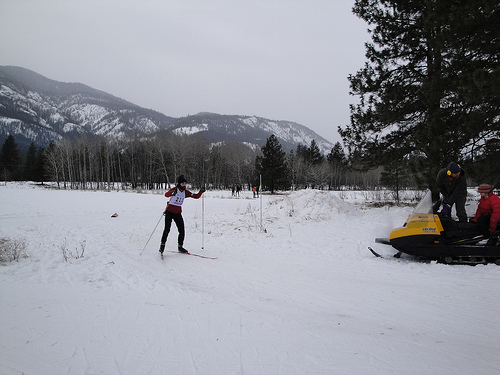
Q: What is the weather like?
A: It is cloudy.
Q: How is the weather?
A: It is cloudy.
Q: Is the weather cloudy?
A: Yes, it is cloudy.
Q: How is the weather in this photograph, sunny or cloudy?
A: It is cloudy.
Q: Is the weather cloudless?
A: No, it is cloudy.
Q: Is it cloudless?
A: No, it is cloudy.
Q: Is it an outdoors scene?
A: Yes, it is outdoors.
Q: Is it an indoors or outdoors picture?
A: It is outdoors.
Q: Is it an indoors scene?
A: No, it is outdoors.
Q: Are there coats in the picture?
A: Yes, there is a coat.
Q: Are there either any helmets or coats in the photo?
A: Yes, there is a coat.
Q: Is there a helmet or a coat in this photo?
A: Yes, there is a coat.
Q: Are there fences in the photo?
A: No, there are no fences.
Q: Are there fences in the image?
A: No, there are no fences.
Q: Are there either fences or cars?
A: No, there are no fences or cars.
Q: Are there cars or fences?
A: No, there are no fences or cars.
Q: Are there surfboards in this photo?
A: No, there are no surfboards.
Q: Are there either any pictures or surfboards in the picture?
A: No, there are no surfboards or pictures.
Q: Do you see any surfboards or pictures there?
A: No, there are no surfboards or pictures.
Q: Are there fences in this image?
A: No, there are no fences.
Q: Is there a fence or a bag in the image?
A: No, there are no fences or bags.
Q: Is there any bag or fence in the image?
A: No, there are no fences or bags.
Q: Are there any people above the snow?
A: Yes, there is a person above the snow.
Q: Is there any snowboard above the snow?
A: No, there is a person above the snow.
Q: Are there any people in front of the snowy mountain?
A: Yes, there is a person in front of the mountain.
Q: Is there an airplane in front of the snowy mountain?
A: No, there is a person in front of the mountain.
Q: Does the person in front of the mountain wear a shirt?
A: Yes, the person wears a shirt.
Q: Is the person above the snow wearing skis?
A: Yes, the person is wearing skis.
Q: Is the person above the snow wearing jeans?
A: No, the person is wearing skis.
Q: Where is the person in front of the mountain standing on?
A: The person is standing on the snow.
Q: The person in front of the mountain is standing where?
A: The person is standing on the snow.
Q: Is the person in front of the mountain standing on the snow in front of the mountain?
A: Yes, the person is standing on the snow.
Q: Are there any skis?
A: Yes, there are skis.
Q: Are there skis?
A: Yes, there are skis.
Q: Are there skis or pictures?
A: Yes, there are skis.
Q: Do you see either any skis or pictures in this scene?
A: Yes, there are skis.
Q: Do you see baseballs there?
A: No, there are no baseballs.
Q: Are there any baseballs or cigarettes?
A: No, there are no baseballs or cigarettes.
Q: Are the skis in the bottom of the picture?
A: Yes, the skis are in the bottom of the image.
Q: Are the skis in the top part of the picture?
A: No, the skis are in the bottom of the image.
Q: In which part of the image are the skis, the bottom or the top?
A: The skis are in the bottom of the image.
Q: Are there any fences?
A: No, there are no fences.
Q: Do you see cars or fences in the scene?
A: No, there are no fences or cars.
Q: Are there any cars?
A: No, there are no cars.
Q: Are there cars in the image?
A: No, there are no cars.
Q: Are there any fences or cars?
A: No, there are no cars or fences.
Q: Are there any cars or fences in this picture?
A: No, there are no cars or fences.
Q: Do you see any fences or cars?
A: No, there are no cars or fences.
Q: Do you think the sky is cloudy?
A: Yes, the sky is cloudy.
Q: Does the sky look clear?
A: No, the sky is cloudy.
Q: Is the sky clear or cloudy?
A: The sky is cloudy.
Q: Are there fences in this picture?
A: No, there are no fences.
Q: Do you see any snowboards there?
A: No, there are no snowboards.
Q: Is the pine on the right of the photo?
A: Yes, the pine is on the right of the image.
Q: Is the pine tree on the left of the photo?
A: No, the pine tree is on the right of the image.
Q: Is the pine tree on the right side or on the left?
A: The pine tree is on the right of the image.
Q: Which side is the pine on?
A: The pine is on the right of the image.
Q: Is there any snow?
A: Yes, there is snow.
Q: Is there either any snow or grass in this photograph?
A: Yes, there is snow.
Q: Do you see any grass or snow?
A: Yes, there is snow.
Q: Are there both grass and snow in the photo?
A: No, there is snow but no grass.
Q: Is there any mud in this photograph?
A: No, there is no mud.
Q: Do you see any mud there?
A: No, there is no mud.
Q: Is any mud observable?
A: No, there is no mud.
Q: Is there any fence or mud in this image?
A: No, there are no mud or fences.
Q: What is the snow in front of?
A: The snow is in front of the mountain.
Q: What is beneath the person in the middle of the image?
A: The snow is beneath the person.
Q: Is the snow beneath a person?
A: Yes, the snow is beneath a person.